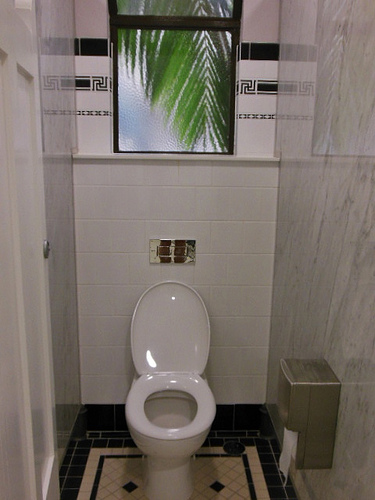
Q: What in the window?
A: Pam tree.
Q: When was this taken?
A: Daytime.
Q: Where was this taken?
A: Bathroom.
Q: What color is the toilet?
A: White.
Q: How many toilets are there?
A: One.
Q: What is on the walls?
A: Tile.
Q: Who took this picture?
A: A photographer.